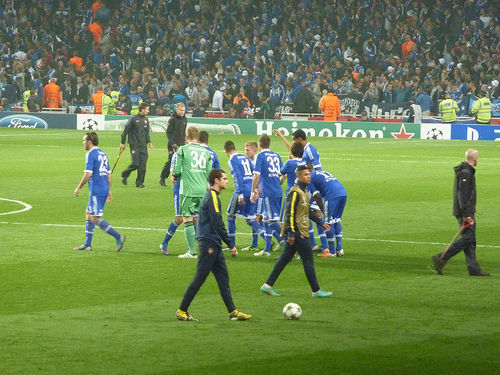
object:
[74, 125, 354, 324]
players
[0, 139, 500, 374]
field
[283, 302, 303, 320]
ball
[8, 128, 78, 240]
turf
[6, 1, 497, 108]
spectators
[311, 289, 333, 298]
shoes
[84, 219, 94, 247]
socks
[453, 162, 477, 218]
jacket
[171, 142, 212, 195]
jersey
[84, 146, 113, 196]
jersey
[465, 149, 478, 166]
head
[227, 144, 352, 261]
uniforms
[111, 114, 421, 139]
sign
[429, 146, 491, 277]
man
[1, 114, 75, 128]
sign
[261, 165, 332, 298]
man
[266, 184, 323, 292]
outfit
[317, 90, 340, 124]
person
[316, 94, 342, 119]
suit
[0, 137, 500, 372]
grass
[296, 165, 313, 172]
hair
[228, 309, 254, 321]
shoes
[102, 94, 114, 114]
jacket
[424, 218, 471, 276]
pitchfork